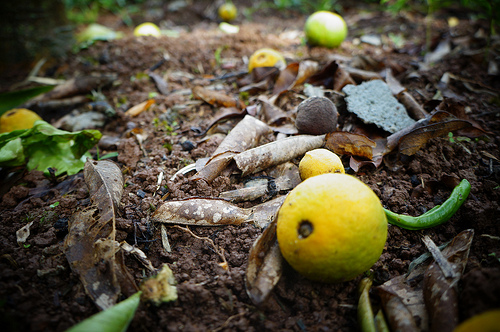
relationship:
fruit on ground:
[275, 172, 388, 279] [0, 1, 499, 329]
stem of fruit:
[295, 219, 311, 240] [275, 172, 388, 279]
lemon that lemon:
[294, 97, 338, 134] [294, 97, 338, 134]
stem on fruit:
[295, 219, 311, 240] [275, 172, 388, 279]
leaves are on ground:
[155, 112, 468, 305] [0, 1, 499, 329]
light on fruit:
[323, 15, 340, 30] [305, 11, 345, 48]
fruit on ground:
[305, 11, 345, 48] [0, 1, 499, 329]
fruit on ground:
[298, 149, 345, 183] [0, 1, 499, 329]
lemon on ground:
[294, 97, 338, 134] [0, 1, 499, 329]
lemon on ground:
[0, 107, 40, 135] [0, 1, 499, 329]